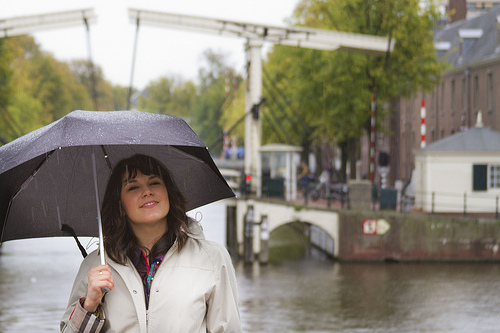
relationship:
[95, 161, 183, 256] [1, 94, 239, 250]
woman with umbrella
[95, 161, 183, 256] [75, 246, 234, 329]
woman wearing jacket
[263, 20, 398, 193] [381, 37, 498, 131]
trees in front of building